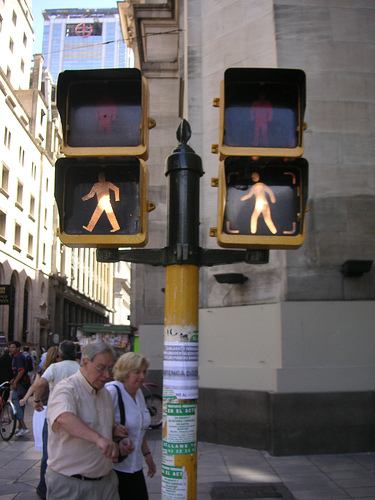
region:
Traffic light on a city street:
[54, 66, 303, 497]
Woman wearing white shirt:
[97, 377, 145, 468]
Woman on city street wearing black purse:
[97, 382, 129, 459]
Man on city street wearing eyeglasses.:
[79, 355, 110, 371]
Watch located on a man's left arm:
[30, 394, 41, 401]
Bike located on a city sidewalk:
[0, 377, 16, 437]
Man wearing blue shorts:
[8, 384, 23, 414]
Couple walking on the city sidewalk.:
[41, 336, 152, 494]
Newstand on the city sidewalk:
[79, 320, 134, 360]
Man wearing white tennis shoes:
[10, 424, 27, 434]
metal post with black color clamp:
[157, 233, 206, 496]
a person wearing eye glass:
[83, 356, 115, 377]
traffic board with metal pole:
[58, 68, 300, 258]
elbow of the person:
[51, 399, 87, 434]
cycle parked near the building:
[0, 367, 18, 444]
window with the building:
[1, 210, 53, 273]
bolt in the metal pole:
[167, 240, 202, 263]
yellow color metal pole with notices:
[162, 265, 203, 498]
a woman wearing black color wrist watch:
[141, 446, 153, 459]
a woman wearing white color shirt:
[112, 383, 157, 464]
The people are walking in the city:
[0, 300, 169, 489]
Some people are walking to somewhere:
[3, 304, 157, 495]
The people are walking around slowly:
[4, 288, 162, 498]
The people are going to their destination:
[4, 298, 165, 493]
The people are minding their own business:
[2, 310, 158, 492]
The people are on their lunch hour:
[8, 312, 158, 497]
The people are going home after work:
[6, 302, 153, 497]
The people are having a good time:
[1, 321, 153, 496]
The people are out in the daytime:
[8, 335, 153, 495]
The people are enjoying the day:
[10, 316, 157, 490]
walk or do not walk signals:
[41, 60, 320, 252]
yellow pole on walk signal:
[152, 261, 212, 497]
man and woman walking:
[34, 333, 160, 498]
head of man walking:
[73, 338, 119, 393]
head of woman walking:
[109, 348, 150, 393]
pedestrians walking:
[4, 329, 81, 451]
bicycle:
[2, 374, 23, 449]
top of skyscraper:
[37, 6, 140, 85]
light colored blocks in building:
[191, 4, 370, 65]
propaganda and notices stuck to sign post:
[154, 337, 206, 499]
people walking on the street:
[6, 343, 173, 480]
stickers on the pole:
[158, 329, 195, 494]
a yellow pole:
[164, 265, 188, 496]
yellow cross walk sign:
[53, 54, 310, 254]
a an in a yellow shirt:
[44, 348, 117, 473]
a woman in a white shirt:
[115, 349, 155, 479]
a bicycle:
[1, 382, 20, 440]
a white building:
[8, 135, 101, 336]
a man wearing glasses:
[68, 342, 114, 398]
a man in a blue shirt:
[8, 342, 33, 437]